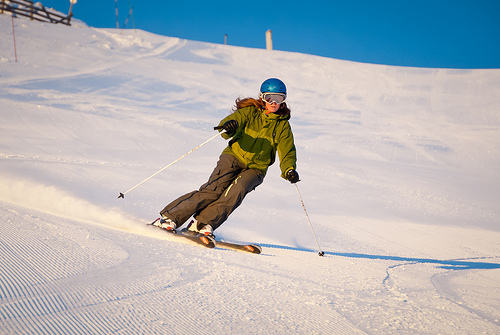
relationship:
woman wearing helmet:
[155, 78, 299, 236] [259, 76, 286, 96]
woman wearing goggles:
[155, 78, 299, 236] [261, 92, 287, 103]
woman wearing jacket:
[155, 78, 299, 236] [217, 105, 299, 174]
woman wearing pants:
[155, 78, 299, 236] [158, 152, 267, 230]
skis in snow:
[147, 224, 262, 256] [2, 14, 500, 334]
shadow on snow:
[241, 237, 498, 273] [2, 14, 500, 334]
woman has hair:
[155, 78, 299, 236] [233, 96, 265, 109]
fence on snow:
[0, 0, 76, 27] [2, 14, 500, 334]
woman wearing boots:
[155, 78, 299, 236] [155, 214, 219, 238]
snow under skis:
[2, 14, 500, 334] [147, 224, 262, 256]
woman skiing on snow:
[155, 78, 299, 236] [2, 14, 500, 334]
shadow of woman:
[241, 237, 498, 273] [155, 78, 299, 236]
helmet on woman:
[259, 76, 286, 96] [155, 78, 299, 236]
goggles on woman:
[261, 92, 287, 103] [155, 78, 299, 236]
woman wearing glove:
[155, 78, 299, 236] [222, 119, 238, 133]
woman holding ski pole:
[155, 78, 299, 236] [116, 128, 227, 201]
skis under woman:
[147, 224, 262, 256] [155, 78, 299, 236]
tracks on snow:
[4, 38, 189, 91] [2, 14, 500, 334]